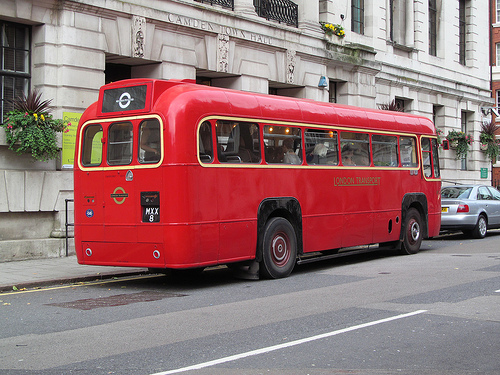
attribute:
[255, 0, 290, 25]
railing — metal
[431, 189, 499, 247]
car — parked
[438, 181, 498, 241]
car — grey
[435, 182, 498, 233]
car — grey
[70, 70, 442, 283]
bus — red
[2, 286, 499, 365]
street — asphalt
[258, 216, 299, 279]
tire — black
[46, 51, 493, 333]
bus — red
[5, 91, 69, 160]
plant — green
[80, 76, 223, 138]
sign — black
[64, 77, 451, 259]
bus — parked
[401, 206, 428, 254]
tires — red and silver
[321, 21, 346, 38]
flowers — yellow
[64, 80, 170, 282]
sidewalk bus — grey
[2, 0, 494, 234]
building — grey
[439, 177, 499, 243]
automobile — silver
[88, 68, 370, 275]
bus — grey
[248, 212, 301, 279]
wheel — black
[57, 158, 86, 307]
rail — black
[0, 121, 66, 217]
sil — window